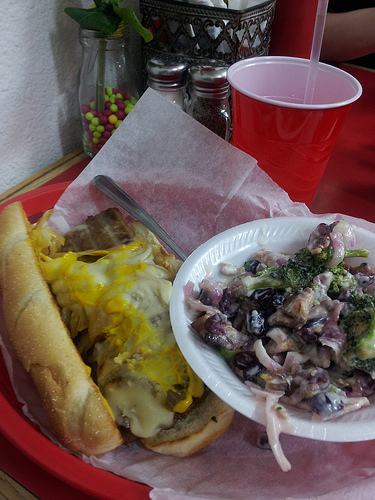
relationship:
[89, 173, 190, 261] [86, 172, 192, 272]
utensil in handle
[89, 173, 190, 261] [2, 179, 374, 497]
utensil in plate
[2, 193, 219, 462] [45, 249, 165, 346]
hot dog in mustard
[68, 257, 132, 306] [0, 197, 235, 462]
mustard in sandwich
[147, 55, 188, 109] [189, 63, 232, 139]
salt in pepper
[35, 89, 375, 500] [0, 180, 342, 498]
paper in basket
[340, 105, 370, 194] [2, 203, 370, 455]
table holding food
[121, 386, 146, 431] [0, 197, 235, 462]
cheese on sandwich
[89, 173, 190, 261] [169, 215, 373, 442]
utensil under plate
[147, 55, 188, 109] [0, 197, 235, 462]
salt behind sandwich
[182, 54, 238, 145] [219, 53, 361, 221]
pepper shaker next cup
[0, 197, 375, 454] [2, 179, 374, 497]
food located on plate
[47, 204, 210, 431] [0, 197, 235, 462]
meat on sandwich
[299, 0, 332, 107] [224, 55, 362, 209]
straw in drink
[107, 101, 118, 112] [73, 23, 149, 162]
object in vase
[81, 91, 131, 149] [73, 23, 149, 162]
object in vase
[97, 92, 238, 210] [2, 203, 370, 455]
paper under food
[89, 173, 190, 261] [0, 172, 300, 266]
utensil on plate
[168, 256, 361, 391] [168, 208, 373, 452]
food in bowl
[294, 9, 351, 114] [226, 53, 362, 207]
straw in cup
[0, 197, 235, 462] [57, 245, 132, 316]
sandwich has cheese